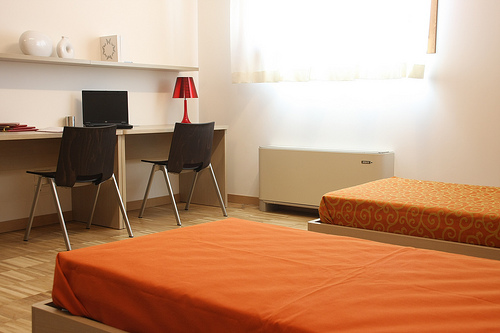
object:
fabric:
[50, 217, 500, 333]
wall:
[1, 1, 200, 229]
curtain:
[227, 0, 437, 83]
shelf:
[0, 53, 199, 72]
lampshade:
[172, 77, 198, 98]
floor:
[2, 201, 320, 332]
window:
[231, 0, 430, 75]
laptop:
[81, 89, 134, 129]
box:
[306, 218, 499, 262]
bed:
[307, 176, 500, 261]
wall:
[200, 2, 499, 196]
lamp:
[172, 76, 198, 123]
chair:
[22, 123, 134, 250]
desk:
[1, 124, 228, 230]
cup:
[65, 115, 76, 127]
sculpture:
[56, 36, 75, 58]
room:
[1, 0, 499, 329]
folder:
[0, 123, 39, 133]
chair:
[138, 121, 228, 226]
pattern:
[322, 197, 499, 247]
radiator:
[258, 146, 394, 212]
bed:
[30, 217, 500, 333]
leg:
[49, 178, 71, 251]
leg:
[113, 177, 134, 238]